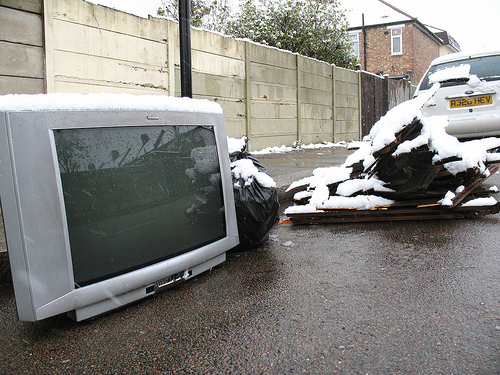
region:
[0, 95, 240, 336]
white tv on the ground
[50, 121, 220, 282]
black screen of tv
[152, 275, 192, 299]
buttons on bottom of screen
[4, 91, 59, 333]
speakers on side of tv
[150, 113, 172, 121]
logo on top of tv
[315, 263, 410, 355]
water on top of asphalt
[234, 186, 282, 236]
black trash bag outside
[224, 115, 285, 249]
black trashbag with snow on top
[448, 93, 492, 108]
yellow licence plate of car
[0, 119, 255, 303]
silver tv on pavement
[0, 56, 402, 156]
concrete wall along lot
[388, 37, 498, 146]
white car on right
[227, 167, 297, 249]
black trash bag on ground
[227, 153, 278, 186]
snow on black bag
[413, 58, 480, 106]
snow on back window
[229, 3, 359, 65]
tree growing by wall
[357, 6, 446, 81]
tall house behind wall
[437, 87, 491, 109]
yellow license plate on car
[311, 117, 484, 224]
stack of pallets on ground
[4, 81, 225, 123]
snow on top of television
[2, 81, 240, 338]
television sitting on pavement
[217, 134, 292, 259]
black snow covered garbage bags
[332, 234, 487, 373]
wet surface of pavement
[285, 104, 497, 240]
pile of trash covered in snow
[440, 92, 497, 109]
license plate on back of car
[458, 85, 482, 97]
company logo on back of car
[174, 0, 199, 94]
black metal street light pole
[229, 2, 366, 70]
trees with green leaves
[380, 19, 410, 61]
white window on red brick building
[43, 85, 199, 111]
this is a snow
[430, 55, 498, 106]
this is a car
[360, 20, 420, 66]
this is a house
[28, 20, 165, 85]
this is a wall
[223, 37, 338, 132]
this is a wall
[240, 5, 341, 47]
this is a tree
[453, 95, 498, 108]
this is a number plate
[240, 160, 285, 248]
this is a paper bag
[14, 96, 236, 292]
this is a tv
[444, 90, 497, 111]
Yellow license plate on rear.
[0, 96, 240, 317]
Old television with snow on top.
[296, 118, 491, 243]
Pile of wood with snow.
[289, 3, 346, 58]
Tree behind brick wall.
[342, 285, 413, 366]
Black pavement wet from rain.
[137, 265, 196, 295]
Programming buttons on old tv.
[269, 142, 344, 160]
Snow on corner of sidewalk.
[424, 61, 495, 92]
Snow on the back of car window.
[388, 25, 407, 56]
Window to upper level of brick building.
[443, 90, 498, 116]
license plate on the car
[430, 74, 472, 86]
wiper on the car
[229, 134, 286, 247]
trash bag on the pavement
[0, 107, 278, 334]
television on the pavement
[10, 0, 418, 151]
fence beside the pavement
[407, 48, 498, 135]
car on the pavement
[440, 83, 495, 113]
A rectangular yellow license plate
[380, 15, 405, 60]
A window on a house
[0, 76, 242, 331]
A television set on the ground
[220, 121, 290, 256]
Snow on black plastic bags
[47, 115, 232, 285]
Reflections on a TV screen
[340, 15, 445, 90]
Bricks on a house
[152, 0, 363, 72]
Green leaves on the trees